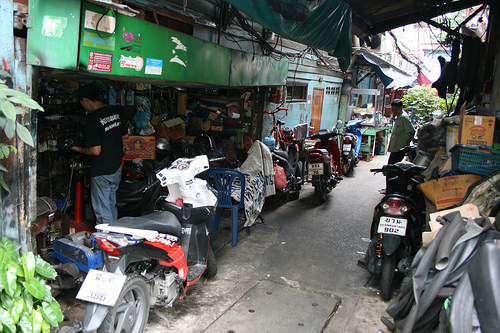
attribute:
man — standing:
[390, 98, 412, 167]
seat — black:
[121, 206, 189, 231]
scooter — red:
[69, 152, 234, 329]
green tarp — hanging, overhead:
[228, 0, 356, 68]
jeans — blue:
[97, 176, 113, 219]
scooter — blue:
[346, 153, 438, 293]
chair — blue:
[203, 161, 260, 247]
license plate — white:
[71, 266, 131, 313]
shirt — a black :
[64, 103, 140, 193]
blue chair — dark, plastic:
[197, 163, 244, 248]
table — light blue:
[398, 89, 483, 193]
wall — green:
[261, 67, 376, 149]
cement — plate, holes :
[238, 247, 336, 331]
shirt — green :
[368, 111, 425, 143]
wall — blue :
[324, 83, 337, 128]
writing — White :
[100, 112, 124, 132]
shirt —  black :
[85, 105, 134, 176]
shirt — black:
[84, 103, 176, 168]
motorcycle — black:
[355, 139, 426, 304]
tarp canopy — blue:
[357, 57, 398, 100]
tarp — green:
[228, 0, 359, 75]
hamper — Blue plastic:
[52, 222, 104, 272]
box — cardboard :
[431, 172, 469, 203]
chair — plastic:
[212, 164, 255, 251]